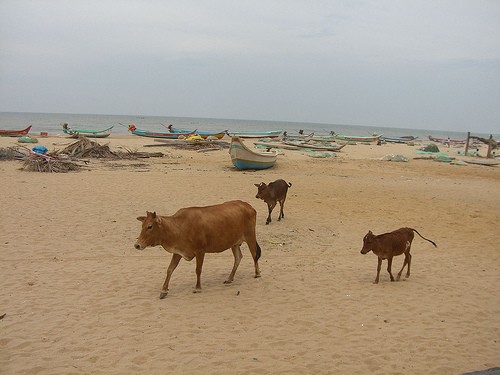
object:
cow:
[133, 199, 263, 298]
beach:
[0, 133, 499, 374]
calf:
[359, 227, 438, 285]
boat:
[228, 133, 285, 172]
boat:
[129, 123, 197, 137]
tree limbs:
[17, 151, 91, 172]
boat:
[60, 124, 114, 137]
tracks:
[99, 158, 497, 175]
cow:
[252, 178, 291, 226]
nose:
[133, 245, 143, 252]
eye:
[146, 225, 151, 230]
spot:
[259, 183, 262, 186]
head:
[251, 182, 266, 199]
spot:
[363, 236, 367, 239]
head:
[358, 229, 375, 257]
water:
[0, 112, 495, 141]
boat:
[369, 132, 418, 143]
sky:
[0, 0, 498, 136]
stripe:
[146, 131, 174, 139]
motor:
[127, 123, 135, 131]